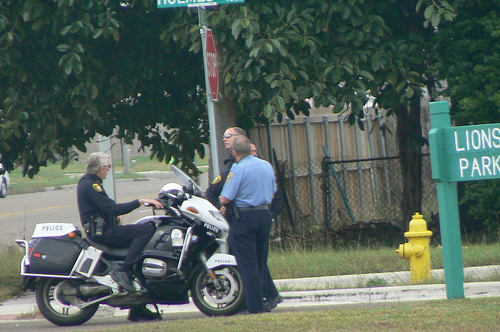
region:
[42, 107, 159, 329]
A cop is riding his bike.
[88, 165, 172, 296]
A cop is riding his bike.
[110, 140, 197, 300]
A cop is riding his bike.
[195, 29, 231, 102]
red stop sign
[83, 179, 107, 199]
police log on shoulder of man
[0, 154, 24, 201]
silver car parked on side of street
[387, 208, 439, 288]
yellow fire hydrant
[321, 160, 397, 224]
chain length fencing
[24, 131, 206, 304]
police office sitting on motorcycle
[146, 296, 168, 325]
black kickstand on motorcycle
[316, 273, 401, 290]
grass growing on side walk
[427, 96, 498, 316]
green wooden sign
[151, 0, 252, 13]
green sign with street name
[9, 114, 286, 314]
police officers chatting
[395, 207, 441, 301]
a yellow fire hydrant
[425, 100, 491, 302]
a green and white wooden sign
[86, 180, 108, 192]
a yellow patch on a uniform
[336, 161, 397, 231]
a black wire fence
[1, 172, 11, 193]
a car parked nearby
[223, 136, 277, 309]
an officer wearing a blue shirt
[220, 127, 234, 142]
a policeman wearing sunglasses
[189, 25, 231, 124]
a red and white stop sign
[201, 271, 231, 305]
the front wheel of a police motorcycle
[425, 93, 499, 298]
Green park sign on street.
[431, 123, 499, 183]
Sign stating the name of the park.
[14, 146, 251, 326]
Police officer on his bike.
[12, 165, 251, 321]
Police bike on the street.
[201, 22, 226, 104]
Stop sign on the street.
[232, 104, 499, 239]
Wooden fence in the background.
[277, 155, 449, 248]
Metal chain link fence in the background.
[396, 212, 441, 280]
Yellow fire hydrant on the street.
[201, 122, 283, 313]
Three police officers on the street.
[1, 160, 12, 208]
Parked car on the street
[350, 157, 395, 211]
metal chain length fencing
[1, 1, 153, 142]
trees with thick green leaves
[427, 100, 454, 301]
green wooden sign post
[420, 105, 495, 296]
green sign with white writing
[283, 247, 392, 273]
grass growing beside road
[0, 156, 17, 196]
car parked on side of road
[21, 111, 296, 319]
three police officers talking